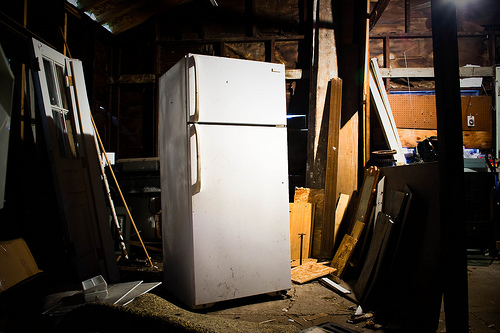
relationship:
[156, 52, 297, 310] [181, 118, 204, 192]
freezer has handle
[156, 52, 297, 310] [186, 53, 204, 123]
freezer has handle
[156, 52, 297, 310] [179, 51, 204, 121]
freezer has handle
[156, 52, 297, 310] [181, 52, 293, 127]
freezer has door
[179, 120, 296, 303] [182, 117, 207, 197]
door has handle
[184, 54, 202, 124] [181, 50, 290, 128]
handle on freezer door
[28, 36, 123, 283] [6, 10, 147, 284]
door on wall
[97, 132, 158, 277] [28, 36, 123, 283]
stick on door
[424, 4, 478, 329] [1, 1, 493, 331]
post in room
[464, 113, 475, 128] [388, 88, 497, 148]
meter on wall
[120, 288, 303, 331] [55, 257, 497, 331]
pad on floor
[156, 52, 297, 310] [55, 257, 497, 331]
freezer on floor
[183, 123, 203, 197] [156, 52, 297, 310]
handle on freezer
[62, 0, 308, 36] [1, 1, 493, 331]
ceiling in room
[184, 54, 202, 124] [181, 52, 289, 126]
handle on freezer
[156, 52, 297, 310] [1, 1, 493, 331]
freezer in room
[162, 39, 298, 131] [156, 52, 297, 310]
freezer on top of freezer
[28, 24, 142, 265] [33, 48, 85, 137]
door has windows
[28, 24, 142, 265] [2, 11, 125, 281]
door leaning on wall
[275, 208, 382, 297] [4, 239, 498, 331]
fiberboard on floor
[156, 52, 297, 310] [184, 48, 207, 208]
freezer has handles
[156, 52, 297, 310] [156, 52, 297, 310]
freezer has freezer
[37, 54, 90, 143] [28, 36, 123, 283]
window on door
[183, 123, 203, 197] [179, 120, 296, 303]
handle on door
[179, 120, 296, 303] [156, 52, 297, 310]
door on freezer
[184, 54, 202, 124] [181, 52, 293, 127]
handle on door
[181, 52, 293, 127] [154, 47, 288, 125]
door on freezer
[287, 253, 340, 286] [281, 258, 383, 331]
plywood on ground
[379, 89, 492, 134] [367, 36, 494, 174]
cork board on wall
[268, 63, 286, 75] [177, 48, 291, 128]
logo on door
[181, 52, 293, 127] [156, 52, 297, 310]
door on freezer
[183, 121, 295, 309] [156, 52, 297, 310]
door on freezer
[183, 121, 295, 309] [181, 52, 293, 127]
door below door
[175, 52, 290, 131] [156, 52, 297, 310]
door on freezer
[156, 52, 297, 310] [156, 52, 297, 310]
freezer on freezer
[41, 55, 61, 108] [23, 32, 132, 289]
window on door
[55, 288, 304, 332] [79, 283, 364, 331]
pad on ground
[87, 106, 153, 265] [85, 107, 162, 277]
handle on mop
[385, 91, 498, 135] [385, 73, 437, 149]
cork board on wall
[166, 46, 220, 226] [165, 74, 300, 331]
handle on fridge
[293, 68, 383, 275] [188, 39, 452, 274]
wood in garage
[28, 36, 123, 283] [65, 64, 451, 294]
door in garage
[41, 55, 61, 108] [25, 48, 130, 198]
window in door